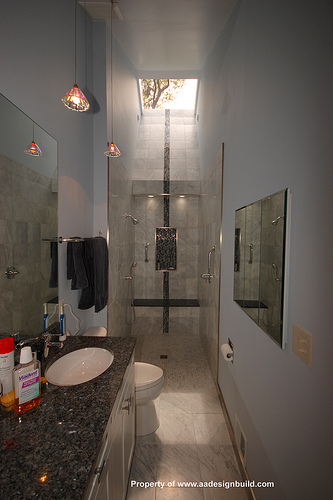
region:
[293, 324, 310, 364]
Light switch panel on the wall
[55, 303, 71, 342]
electric toothbrush on a charger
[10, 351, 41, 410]
mouthwash is on the counter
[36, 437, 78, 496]
the counter tops are granite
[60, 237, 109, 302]
towels hanging on a rack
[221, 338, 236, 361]
toilet paper on a roll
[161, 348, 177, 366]
shower drain is on the ground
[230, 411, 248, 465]
vent panel on the wall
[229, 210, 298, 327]
large mirror hanging on the wall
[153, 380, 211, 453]
sun shine from the sky light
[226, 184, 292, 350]
large mirror on the wall of the bathroom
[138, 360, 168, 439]
front of the white porcelain toilet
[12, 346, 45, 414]
bottle of Viadent mouthwash on the counter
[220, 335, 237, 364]
white roll of toilet paper in the holder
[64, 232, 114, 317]
black fluffy towels hanging over the toilet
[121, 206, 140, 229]
silver shower head attached to the wall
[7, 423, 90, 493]
black and grey granite counter top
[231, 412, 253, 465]
white air conditioning vent near the floor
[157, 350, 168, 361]
square drain in the middle of the shower floor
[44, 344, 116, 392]
oval white sink on the counter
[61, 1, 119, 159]
light fixtures on the ceiling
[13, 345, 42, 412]
a bottle on a counter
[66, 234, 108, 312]
dark gray towels on a rack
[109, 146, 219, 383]
a shower in a bathroom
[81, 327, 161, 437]
a white toilet in a bathroom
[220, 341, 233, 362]
a white roll of toilet paper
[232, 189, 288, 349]
a mirror on the wall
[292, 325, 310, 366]
light switches on the wall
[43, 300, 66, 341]
electric toothbrushes on a counter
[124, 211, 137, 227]
a shower head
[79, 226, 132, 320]
black towel on towel rack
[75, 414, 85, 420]
black and granite counter top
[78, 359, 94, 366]
white oval porcelain sink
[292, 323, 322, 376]
beige electrical switch on wall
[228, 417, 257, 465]
white air vent on wall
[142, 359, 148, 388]
white toilet with seat down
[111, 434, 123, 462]
cabinet doors are white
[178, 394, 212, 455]
light reflecting off gray floor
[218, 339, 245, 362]
white toilet paper on roll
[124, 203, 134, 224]
stainless shower head on wall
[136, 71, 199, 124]
an open skylight in the shower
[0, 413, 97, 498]
a granite bathroom vanity top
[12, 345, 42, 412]
a bottle of mouthwash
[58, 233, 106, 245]
a bath towel rack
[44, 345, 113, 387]
a porcelain sink on the vanity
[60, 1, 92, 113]
a ceiling hanging lamp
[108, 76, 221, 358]
the enclosed shower stall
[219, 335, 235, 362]
the toilet paper dispenser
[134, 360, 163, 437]
the white ceramic toilet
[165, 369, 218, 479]
the bathroom floor tiles